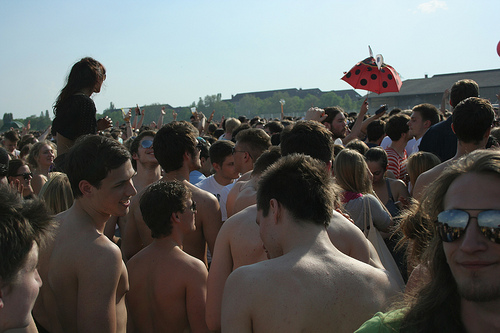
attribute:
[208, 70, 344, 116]
buildings — distant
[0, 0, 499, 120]
sky — pale blue, blue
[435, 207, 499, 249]
sunglasses — reflective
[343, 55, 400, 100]
umbrella — black, red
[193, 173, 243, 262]
shirt — white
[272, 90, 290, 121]
road sign — distant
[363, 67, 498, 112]
house — distant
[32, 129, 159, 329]
guy — side-looking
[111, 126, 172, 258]
man — looking up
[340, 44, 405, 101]
umbrella — pictured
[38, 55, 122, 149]
woman — pictured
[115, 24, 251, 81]
sky — clear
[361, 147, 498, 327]
man smiling — pictured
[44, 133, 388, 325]
men — shirtless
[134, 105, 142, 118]
bottle — held up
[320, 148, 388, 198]
bag — over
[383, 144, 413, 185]
shirt — striped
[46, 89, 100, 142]
shirt — black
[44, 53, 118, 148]
girl — shoulder-sitting